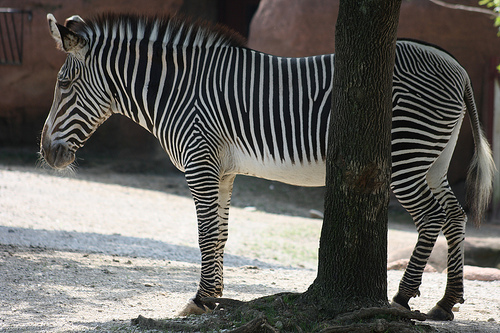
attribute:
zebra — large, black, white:
[28, 19, 435, 329]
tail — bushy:
[429, 66, 490, 207]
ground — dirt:
[80, 198, 421, 329]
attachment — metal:
[0, 4, 23, 59]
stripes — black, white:
[160, 58, 317, 152]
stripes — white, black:
[144, 62, 307, 138]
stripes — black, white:
[143, 46, 337, 145]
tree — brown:
[304, 6, 407, 329]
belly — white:
[230, 133, 342, 209]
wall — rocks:
[8, 6, 495, 204]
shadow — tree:
[8, 226, 230, 308]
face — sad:
[36, 39, 121, 172]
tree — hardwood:
[334, 32, 394, 318]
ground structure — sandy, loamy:
[14, 162, 468, 318]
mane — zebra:
[58, 15, 243, 54]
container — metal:
[12, 8, 36, 59]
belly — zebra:
[234, 167, 333, 187]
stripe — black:
[133, 39, 149, 119]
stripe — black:
[109, 34, 121, 116]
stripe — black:
[182, 129, 205, 149]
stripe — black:
[390, 102, 444, 123]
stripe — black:
[401, 185, 431, 205]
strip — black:
[183, 150, 203, 169]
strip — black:
[300, 56, 311, 162]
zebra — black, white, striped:
[31, 9, 491, 326]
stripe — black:
[260, 52, 274, 156]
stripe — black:
[249, 48, 261, 156]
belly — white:
[230, 137, 333, 193]